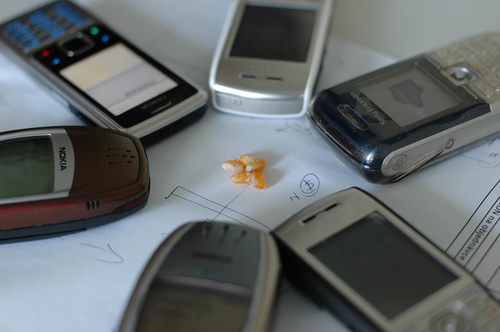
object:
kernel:
[251, 171, 265, 189]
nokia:
[58, 144, 68, 172]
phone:
[1, 125, 153, 240]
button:
[36, 48, 55, 58]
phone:
[268, 185, 500, 332]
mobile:
[208, 1, 334, 119]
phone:
[1, 2, 209, 147]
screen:
[228, 0, 318, 65]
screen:
[60, 42, 179, 118]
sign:
[299, 171, 323, 198]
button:
[89, 25, 99, 35]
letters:
[188, 250, 235, 264]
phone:
[306, 31, 500, 185]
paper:
[198, 122, 307, 157]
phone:
[117, 219, 283, 331]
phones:
[0, 0, 500, 329]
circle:
[130, 91, 388, 237]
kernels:
[221, 151, 268, 189]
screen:
[304, 209, 459, 319]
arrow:
[68, 237, 126, 265]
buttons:
[0, 2, 89, 49]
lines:
[164, 182, 274, 234]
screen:
[0, 134, 55, 200]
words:
[459, 199, 500, 263]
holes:
[204, 220, 252, 247]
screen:
[132, 278, 253, 331]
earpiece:
[238, 72, 286, 84]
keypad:
[430, 30, 500, 104]